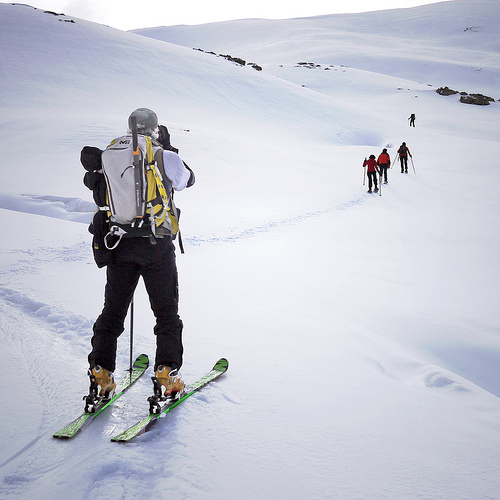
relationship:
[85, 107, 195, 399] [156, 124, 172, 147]
skier holding hand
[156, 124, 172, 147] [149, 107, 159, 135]
hand to face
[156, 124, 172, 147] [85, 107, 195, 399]
hand belongs to skier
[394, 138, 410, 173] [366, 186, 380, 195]
person wearing skis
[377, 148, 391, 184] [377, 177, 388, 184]
skier wearing skis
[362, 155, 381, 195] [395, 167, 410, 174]
person wearing skis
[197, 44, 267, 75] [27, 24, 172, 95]
rocks showing through snow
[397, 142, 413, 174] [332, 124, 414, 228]
person on a trail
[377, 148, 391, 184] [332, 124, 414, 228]
skier on a trail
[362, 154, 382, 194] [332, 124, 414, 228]
person on a trail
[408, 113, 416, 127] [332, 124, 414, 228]
skier on a trail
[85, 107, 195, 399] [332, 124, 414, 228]
skier on a trail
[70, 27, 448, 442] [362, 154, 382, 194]
skier photographs person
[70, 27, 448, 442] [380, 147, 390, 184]
skier photographs skier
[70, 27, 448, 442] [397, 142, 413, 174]
skier photographs person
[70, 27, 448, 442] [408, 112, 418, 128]
skier photographs skier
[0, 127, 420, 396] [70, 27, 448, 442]
trail ahead of skier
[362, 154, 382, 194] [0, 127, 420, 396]
person on trail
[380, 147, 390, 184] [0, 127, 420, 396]
skier on trail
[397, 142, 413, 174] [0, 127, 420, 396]
person on trail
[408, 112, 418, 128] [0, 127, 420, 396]
skier on trail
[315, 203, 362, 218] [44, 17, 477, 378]
track in snow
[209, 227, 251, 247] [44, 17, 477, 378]
track in snow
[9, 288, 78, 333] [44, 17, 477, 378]
track in snow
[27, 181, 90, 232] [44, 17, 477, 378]
track in snow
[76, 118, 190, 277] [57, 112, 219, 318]
backpack with gear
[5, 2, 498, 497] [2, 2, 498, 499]
ground full of snow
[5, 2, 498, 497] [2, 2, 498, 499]
ground has snow